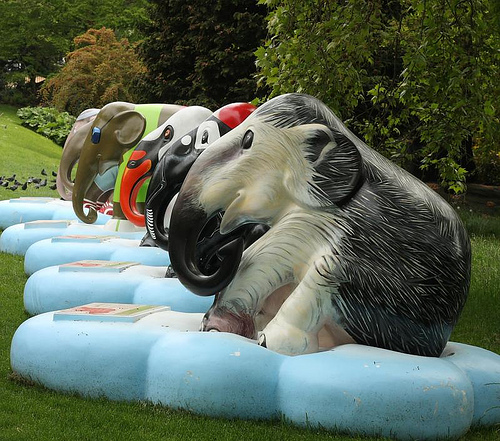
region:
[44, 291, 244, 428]
blue foundation for animal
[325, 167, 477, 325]
black paint on animal sculpture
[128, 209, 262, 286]
trunk of elephant statue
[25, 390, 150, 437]
grass under the statues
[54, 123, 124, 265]
dark green trunk of statue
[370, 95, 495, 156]
leaves off the bark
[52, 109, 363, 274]
line of animal statues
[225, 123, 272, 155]
eye of elephant statue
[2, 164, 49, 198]
birds on the grass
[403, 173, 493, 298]
back of the statue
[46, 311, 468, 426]
the block is blue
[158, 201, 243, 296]
the trunk is black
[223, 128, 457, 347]
the elephant is grey and white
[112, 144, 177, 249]
the trunk is red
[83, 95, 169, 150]
the strip is blue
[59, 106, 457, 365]
the elephants are five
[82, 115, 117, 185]
the eye has a patch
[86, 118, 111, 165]
the patch is blue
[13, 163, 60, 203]
the doves are on the grass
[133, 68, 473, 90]
trees are in the background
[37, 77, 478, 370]
Multiple stone elephants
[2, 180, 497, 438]
These are blue stones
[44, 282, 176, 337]
Sign on the stone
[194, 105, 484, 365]
Animal is black and white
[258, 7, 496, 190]
In the background, there are trees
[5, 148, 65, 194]
Birds walking around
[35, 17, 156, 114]
This tree is brown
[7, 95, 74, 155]
Bushes on the ground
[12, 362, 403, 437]
Grass against the stone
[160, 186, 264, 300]
trunks are black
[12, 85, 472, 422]
five elephants statues in a row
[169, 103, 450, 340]
black and white elephant statute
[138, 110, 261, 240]
red, black, and white elephant statute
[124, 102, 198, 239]
elephant statute with red trunk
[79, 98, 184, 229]
elephant with green on torso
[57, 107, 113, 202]
last elephant statute in the lin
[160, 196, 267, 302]
black trunk of first elephant statute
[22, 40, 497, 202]
tree line behind elephant statutes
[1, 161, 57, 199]
flock of birds behind elephant statutes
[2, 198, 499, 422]
blue bases of elephant statutes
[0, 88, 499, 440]
statue of an elephant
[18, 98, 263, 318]
statue of an elephant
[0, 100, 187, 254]
statue of an elephant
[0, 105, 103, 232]
statue of an elephant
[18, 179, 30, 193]
bird in the grass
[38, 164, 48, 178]
bird in the grass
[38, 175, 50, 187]
bird in the grass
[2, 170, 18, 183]
bird in the grass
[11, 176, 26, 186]
bird in the grass